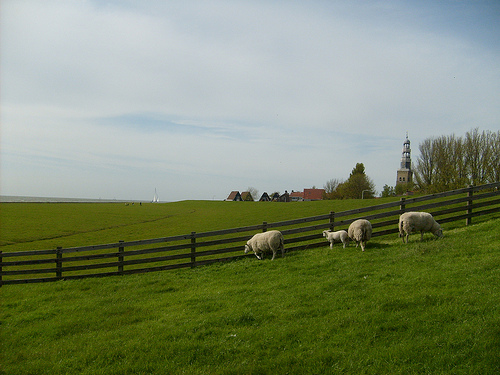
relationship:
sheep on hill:
[245, 230, 284, 265] [0, 187, 499, 374]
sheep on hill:
[319, 230, 345, 248] [0, 187, 499, 374]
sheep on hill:
[349, 221, 376, 254] [0, 187, 499, 374]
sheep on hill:
[396, 212, 443, 245] [0, 187, 499, 374]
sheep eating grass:
[245, 230, 284, 265] [0, 187, 499, 374]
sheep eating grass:
[319, 230, 345, 248] [0, 187, 499, 374]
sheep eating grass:
[349, 221, 376, 254] [0, 187, 499, 374]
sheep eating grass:
[396, 212, 443, 245] [0, 187, 499, 374]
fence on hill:
[0, 182, 499, 289] [0, 187, 499, 374]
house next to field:
[225, 192, 242, 207] [0, 187, 499, 374]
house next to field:
[241, 192, 255, 203] [0, 187, 499, 374]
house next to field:
[260, 192, 274, 202] [0, 187, 499, 374]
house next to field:
[269, 193, 281, 202] [0, 187, 499, 374]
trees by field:
[411, 142, 438, 195] [0, 187, 499, 374]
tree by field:
[434, 138, 450, 195] [0, 187, 499, 374]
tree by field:
[452, 139, 466, 186] [0, 187, 499, 374]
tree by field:
[469, 129, 486, 181] [0, 187, 499, 374]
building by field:
[394, 133, 413, 197] [0, 187, 499, 374]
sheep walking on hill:
[245, 230, 284, 265] [0, 187, 499, 374]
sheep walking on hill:
[319, 230, 345, 248] [0, 187, 499, 374]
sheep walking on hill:
[349, 221, 376, 254] [0, 187, 499, 374]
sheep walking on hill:
[396, 212, 443, 245] [0, 187, 499, 374]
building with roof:
[302, 188, 328, 206] [303, 189, 330, 201]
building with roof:
[289, 191, 305, 204] [291, 192, 305, 197]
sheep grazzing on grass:
[245, 230, 284, 265] [0, 187, 499, 374]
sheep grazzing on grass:
[319, 230, 345, 248] [0, 187, 499, 374]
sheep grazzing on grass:
[349, 221, 376, 254] [0, 187, 499, 374]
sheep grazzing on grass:
[396, 212, 443, 245] [0, 187, 499, 374]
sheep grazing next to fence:
[245, 230, 284, 265] [0, 182, 499, 289]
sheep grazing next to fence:
[319, 230, 345, 248] [0, 182, 499, 289]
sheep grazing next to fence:
[349, 221, 376, 254] [0, 182, 499, 289]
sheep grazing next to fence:
[396, 212, 443, 245] [0, 182, 499, 289]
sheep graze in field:
[245, 230, 284, 265] [0, 187, 499, 374]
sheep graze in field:
[319, 230, 345, 248] [0, 187, 499, 374]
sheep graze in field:
[349, 221, 376, 254] [0, 187, 499, 374]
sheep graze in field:
[396, 212, 443, 245] [0, 187, 499, 374]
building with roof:
[289, 191, 305, 204] [303, 189, 330, 201]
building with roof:
[271, 192, 284, 204] [261, 192, 269, 200]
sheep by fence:
[245, 230, 284, 265] [0, 182, 499, 289]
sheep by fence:
[319, 230, 345, 248] [0, 182, 499, 289]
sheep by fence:
[349, 221, 376, 254] [0, 182, 499, 289]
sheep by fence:
[396, 212, 443, 245] [0, 182, 499, 289]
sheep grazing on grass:
[245, 230, 284, 265] [0, 187, 499, 374]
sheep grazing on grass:
[319, 230, 345, 248] [0, 187, 499, 374]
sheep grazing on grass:
[349, 221, 376, 254] [0, 187, 499, 374]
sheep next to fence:
[319, 230, 345, 248] [0, 182, 499, 289]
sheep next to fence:
[245, 230, 284, 265] [0, 182, 499, 289]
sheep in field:
[245, 230, 284, 265] [0, 187, 499, 374]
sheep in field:
[319, 230, 345, 248] [0, 187, 499, 374]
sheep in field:
[349, 221, 376, 254] [0, 187, 499, 374]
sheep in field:
[396, 212, 443, 245] [0, 187, 499, 374]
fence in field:
[0, 182, 499, 289] [0, 187, 499, 374]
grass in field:
[0, 187, 499, 374] [0, 187, 499, 374]